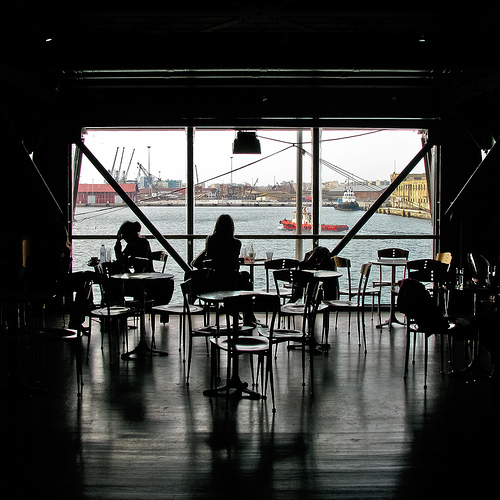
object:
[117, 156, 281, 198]
structures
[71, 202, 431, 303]
water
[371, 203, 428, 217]
ground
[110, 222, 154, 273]
woman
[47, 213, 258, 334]
people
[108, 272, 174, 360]
table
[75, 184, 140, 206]
building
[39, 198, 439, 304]
harbor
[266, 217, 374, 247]
tugboat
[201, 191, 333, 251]
water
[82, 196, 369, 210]
partition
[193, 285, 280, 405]
table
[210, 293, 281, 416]
chair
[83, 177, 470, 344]
seaport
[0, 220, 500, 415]
seating area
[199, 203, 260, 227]
water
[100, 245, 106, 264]
plastic bottle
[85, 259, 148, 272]
table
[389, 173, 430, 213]
building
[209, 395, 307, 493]
shadows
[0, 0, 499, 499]
room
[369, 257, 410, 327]
table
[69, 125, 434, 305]
window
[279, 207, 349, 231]
boat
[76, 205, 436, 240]
water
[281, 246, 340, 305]
person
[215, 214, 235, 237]
head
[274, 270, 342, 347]
table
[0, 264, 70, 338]
table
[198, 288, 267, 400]
table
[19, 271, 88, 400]
chair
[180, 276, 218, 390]
chair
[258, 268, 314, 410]
chair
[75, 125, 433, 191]
sky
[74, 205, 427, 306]
water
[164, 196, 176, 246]
water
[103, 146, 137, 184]
cranes